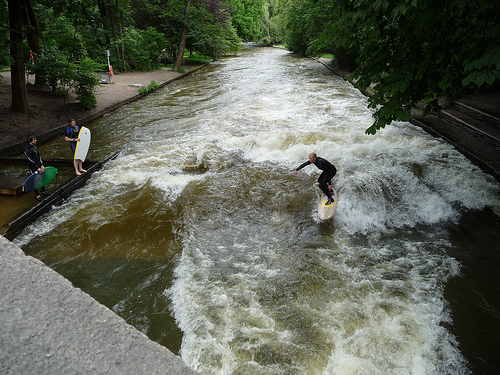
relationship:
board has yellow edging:
[73, 126, 91, 162] [74, 126, 84, 161]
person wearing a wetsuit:
[64, 117, 88, 175] [64, 126, 84, 156]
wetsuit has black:
[64, 126, 84, 156] [63, 122, 80, 151]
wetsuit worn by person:
[64, 126, 84, 156] [64, 117, 88, 175]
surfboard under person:
[316, 185, 338, 223] [293, 152, 337, 205]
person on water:
[293, 152, 337, 205] [0, 42, 499, 375]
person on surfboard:
[293, 152, 337, 205] [316, 185, 338, 223]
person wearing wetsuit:
[293, 152, 337, 205] [295, 156, 336, 206]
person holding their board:
[64, 117, 88, 175] [73, 126, 91, 162]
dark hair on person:
[26, 133, 38, 145] [27, 134, 51, 202]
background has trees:
[1, 1, 500, 137] [0, 0, 499, 140]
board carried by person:
[73, 126, 91, 162] [64, 117, 88, 175]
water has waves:
[0, 42, 499, 375] [98, 96, 500, 374]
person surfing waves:
[293, 152, 337, 205] [98, 96, 500, 374]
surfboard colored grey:
[316, 185, 338, 223] [319, 186, 337, 220]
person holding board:
[27, 134, 51, 202] [22, 165, 60, 192]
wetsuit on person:
[295, 156, 336, 206] [293, 152, 337, 205]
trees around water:
[0, 0, 499, 140] [0, 42, 499, 375]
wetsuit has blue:
[64, 126, 84, 156] [64, 123, 81, 151]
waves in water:
[98, 96, 500, 374] [0, 42, 499, 375]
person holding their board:
[27, 134, 51, 202] [22, 165, 60, 192]